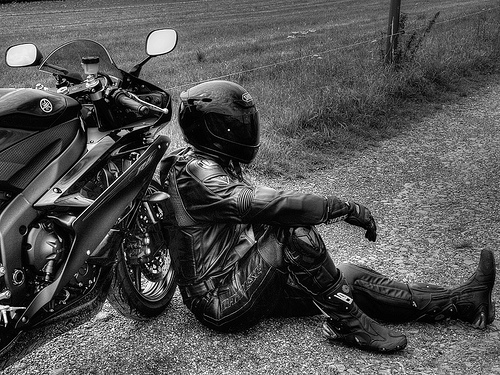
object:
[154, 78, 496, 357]
motorcyclist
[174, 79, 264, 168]
helmet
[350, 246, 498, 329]
boot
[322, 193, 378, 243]
glove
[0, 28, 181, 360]
motorcycle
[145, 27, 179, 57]
mirror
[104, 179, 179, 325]
tire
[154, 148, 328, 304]
jacket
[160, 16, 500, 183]
grass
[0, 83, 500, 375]
road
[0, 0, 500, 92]
fence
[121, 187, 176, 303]
rim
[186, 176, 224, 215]
leather